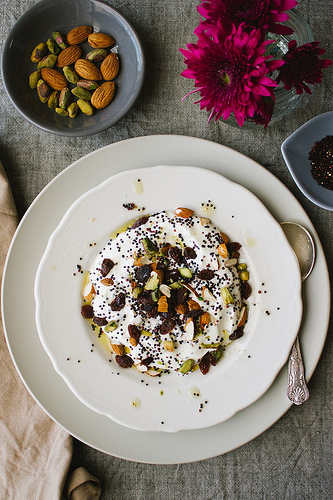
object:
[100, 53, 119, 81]
nut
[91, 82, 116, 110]
nut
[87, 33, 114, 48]
nut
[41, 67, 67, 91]
nut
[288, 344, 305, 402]
design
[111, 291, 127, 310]
raisin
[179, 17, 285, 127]
flowers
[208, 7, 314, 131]
jar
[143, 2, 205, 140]
creases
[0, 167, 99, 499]
napkin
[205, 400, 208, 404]
seeds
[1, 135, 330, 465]
plate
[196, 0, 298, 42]
flowers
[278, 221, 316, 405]
spoon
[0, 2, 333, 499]
tablecloth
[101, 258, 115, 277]
raisin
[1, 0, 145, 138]
almonds/pistachios/bowl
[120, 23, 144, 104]
reflecting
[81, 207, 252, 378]
dessert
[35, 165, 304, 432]
bowl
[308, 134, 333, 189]
poppy seeds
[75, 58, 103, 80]
almonds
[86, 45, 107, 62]
pistachios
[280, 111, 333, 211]
bowl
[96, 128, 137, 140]
bad sentence